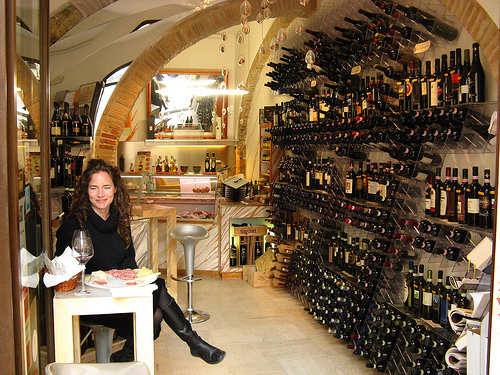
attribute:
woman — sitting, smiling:
[56, 160, 226, 365]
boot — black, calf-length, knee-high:
[161, 297, 226, 364]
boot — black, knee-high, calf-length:
[110, 335, 134, 361]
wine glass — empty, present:
[72, 238, 94, 297]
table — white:
[53, 274, 156, 375]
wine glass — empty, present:
[71, 229, 89, 283]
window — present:
[89, 59, 131, 146]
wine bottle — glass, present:
[467, 43, 484, 102]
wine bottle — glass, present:
[413, 16, 459, 42]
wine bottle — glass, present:
[345, 161, 357, 200]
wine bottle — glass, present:
[402, 260, 413, 312]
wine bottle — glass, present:
[421, 271, 436, 321]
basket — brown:
[41, 266, 80, 292]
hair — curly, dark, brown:
[63, 159, 132, 251]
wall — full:
[234, 0, 498, 375]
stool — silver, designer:
[169, 223, 210, 324]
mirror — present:
[145, 69, 229, 140]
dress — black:
[54, 207, 165, 336]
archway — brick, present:
[92, 0, 318, 165]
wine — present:
[50, 102, 63, 138]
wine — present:
[80, 105, 92, 135]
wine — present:
[61, 102, 72, 139]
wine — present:
[229, 236, 238, 268]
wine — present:
[478, 169, 493, 231]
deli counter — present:
[126, 173, 218, 274]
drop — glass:
[236, 55, 245, 66]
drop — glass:
[306, 49, 315, 65]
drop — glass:
[239, 1, 252, 17]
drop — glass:
[222, 31, 228, 42]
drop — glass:
[276, 28, 287, 43]